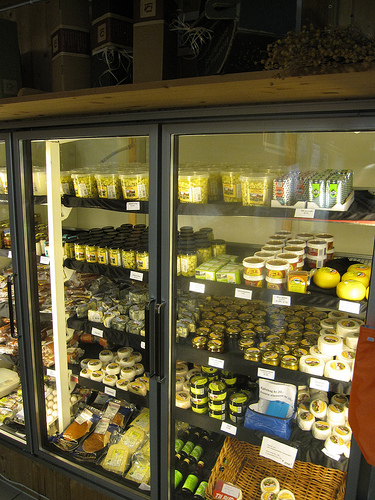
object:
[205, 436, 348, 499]
basket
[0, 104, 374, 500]
cooler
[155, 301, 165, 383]
handles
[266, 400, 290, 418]
pouch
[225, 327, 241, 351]
jars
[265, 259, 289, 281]
container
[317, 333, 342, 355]
goods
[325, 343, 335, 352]
plastic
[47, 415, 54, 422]
eggs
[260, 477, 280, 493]
items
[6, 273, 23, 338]
handle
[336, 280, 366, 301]
cheese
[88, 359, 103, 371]
cheese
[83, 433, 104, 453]
sandwiches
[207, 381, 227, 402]
jars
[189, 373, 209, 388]
lids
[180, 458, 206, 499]
bottles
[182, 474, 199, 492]
labels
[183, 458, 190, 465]
lids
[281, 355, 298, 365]
lids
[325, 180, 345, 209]
boxes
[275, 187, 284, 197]
labels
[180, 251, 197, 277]
bottles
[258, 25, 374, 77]
flowers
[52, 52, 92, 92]
box